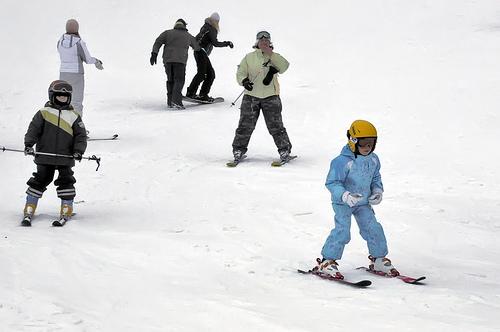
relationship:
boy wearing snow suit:
[7, 79, 104, 231] [22, 71, 114, 244]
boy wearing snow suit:
[303, 105, 420, 312] [318, 111, 457, 310]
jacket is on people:
[235, 48, 289, 96] [231, 31, 293, 161]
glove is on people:
[242, 77, 254, 89] [231, 31, 293, 161]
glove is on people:
[262, 64, 279, 84] [231, 31, 293, 161]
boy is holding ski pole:
[23, 79, 88, 219] [0, 142, 106, 166]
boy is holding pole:
[23, 79, 88, 219] [0, 146, 101, 172]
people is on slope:
[124, 9, 320, 173] [3, 2, 494, 327]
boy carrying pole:
[23, 79, 88, 219] [0, 144, 100, 169]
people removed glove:
[231, 31, 293, 161] [262, 62, 274, 77]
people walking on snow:
[149, 18, 203, 109] [1, 1, 499, 330]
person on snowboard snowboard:
[186, 12, 234, 101] [180, 94, 224, 105]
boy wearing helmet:
[315, 120, 400, 279] [325, 114, 392, 222]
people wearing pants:
[231, 31, 293, 161] [226, 96, 299, 162]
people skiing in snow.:
[14, 20, 395, 274] [393, 291, 457, 326]